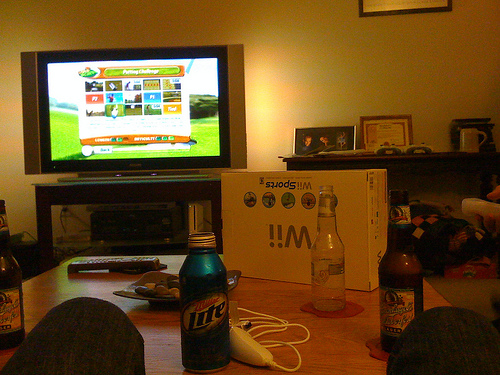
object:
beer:
[178, 232, 230, 374]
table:
[0, 254, 455, 375]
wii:
[229, 326, 273, 367]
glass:
[310, 184, 345, 311]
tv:
[19, 44, 248, 178]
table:
[34, 178, 223, 272]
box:
[220, 168, 391, 291]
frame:
[359, 114, 414, 149]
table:
[281, 149, 497, 171]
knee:
[0, 297, 144, 375]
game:
[47, 58, 221, 162]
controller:
[462, 184, 500, 230]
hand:
[487, 186, 498, 200]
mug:
[460, 128, 488, 154]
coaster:
[299, 299, 364, 319]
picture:
[293, 125, 357, 156]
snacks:
[134, 275, 180, 297]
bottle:
[378, 189, 423, 352]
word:
[269, 224, 312, 249]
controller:
[229, 307, 310, 372]